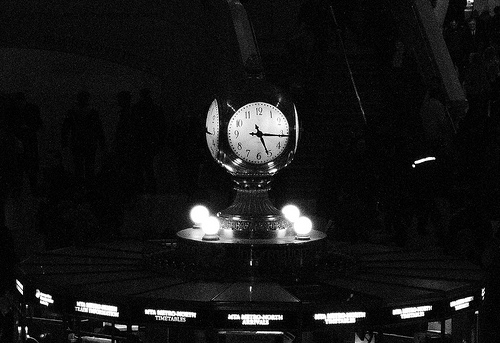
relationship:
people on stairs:
[249, 0, 446, 196] [252, 14, 462, 238]